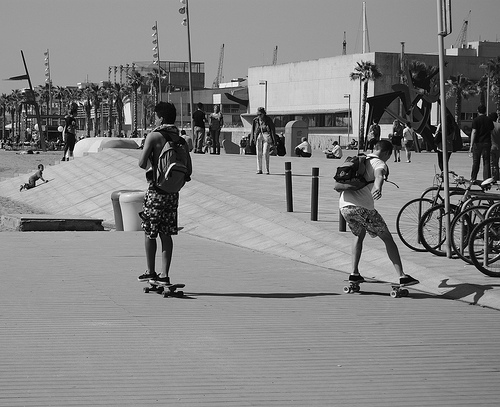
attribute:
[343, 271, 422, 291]
sneakers — black, white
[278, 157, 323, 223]
poles — black, round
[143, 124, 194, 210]
bakcpack — black, white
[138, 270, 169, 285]
shoes — black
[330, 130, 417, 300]
boy — taller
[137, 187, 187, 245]
shorts — patterned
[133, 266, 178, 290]
shoes — black , white, tennis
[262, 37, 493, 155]
building — large, white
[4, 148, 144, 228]
slope — concrete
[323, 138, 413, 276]
person — young